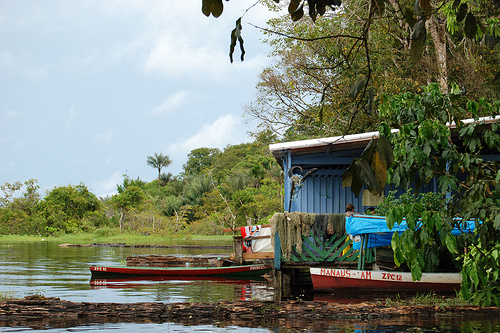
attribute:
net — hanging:
[303, 219, 336, 260]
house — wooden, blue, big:
[263, 140, 386, 214]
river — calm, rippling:
[9, 246, 65, 287]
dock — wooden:
[237, 219, 291, 257]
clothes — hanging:
[283, 205, 375, 243]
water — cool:
[210, 282, 224, 294]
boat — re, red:
[79, 235, 243, 300]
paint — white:
[315, 278, 321, 298]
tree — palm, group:
[370, 50, 443, 129]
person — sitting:
[342, 198, 354, 220]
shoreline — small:
[183, 235, 204, 247]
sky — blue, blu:
[98, 35, 137, 74]